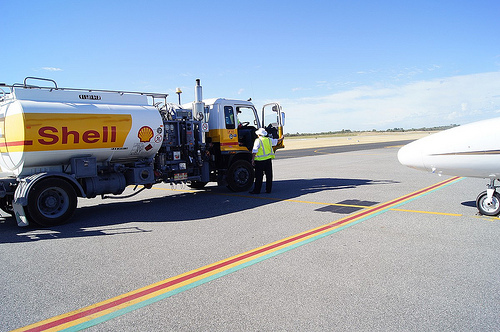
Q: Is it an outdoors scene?
A: Yes, it is outdoors.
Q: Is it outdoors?
A: Yes, it is outdoors.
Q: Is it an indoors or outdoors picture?
A: It is outdoors.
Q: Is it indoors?
A: No, it is outdoors.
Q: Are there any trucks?
A: Yes, there is a truck.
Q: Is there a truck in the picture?
A: Yes, there is a truck.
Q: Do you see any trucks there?
A: Yes, there is a truck.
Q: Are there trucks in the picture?
A: Yes, there is a truck.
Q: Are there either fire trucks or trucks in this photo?
A: Yes, there is a truck.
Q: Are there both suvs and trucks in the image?
A: No, there is a truck but no suvs.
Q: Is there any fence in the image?
A: No, there are no fences.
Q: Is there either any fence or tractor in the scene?
A: No, there are no fences or tractors.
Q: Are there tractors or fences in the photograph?
A: No, there are no fences or tractors.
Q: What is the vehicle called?
A: The vehicle is a truck.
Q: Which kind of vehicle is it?
A: The vehicle is a truck.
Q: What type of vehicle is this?
A: This is a truck.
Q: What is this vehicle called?
A: This is a truck.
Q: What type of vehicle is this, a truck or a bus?
A: This is a truck.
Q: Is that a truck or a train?
A: That is a truck.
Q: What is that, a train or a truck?
A: That is a truck.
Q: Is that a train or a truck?
A: That is a truck.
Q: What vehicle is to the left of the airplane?
A: The vehicle is a truck.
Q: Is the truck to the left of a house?
A: No, the truck is to the left of an airplane.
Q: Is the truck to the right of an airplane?
A: No, the truck is to the left of an airplane.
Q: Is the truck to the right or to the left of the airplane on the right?
A: The truck is to the left of the plane.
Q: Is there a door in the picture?
A: Yes, there is a door.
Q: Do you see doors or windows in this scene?
A: Yes, there is a door.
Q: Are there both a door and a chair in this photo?
A: No, there is a door but no chairs.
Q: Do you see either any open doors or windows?
A: Yes, there is an open door.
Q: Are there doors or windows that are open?
A: Yes, the door is open.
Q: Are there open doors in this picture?
A: Yes, there is an open door.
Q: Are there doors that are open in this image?
A: Yes, there is an open door.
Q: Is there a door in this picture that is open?
A: Yes, there is an open door.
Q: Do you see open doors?
A: Yes, there is an open door.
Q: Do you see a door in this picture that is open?
A: Yes, there is a door that is open.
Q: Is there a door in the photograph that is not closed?
A: Yes, there is a open door.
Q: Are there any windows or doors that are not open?
A: No, there is a door but it is open.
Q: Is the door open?
A: Yes, the door is open.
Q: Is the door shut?
A: No, the door is open.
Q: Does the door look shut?
A: No, the door is open.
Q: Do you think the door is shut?
A: No, the door is open.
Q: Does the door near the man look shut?
A: No, the door is open.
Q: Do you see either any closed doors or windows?
A: No, there is a door but it is open.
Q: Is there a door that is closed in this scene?
A: No, there is a door but it is open.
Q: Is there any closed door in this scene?
A: No, there is a door but it is open.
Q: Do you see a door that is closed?
A: No, there is a door but it is open.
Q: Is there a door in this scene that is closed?
A: No, there is a door but it is open.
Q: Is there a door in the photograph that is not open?
A: No, there is a door but it is open.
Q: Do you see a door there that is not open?
A: No, there is a door but it is open.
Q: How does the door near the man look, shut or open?
A: The door is open.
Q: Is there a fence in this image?
A: No, there are no fences.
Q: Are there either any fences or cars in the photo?
A: No, there are no fences or cars.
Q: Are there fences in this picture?
A: No, there are no fences.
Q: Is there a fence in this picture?
A: No, there are no fences.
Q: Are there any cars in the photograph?
A: No, there are no cars.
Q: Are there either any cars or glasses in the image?
A: No, there are no cars or glasses.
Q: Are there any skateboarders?
A: No, there are no skateboarders.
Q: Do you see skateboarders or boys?
A: No, there are no skateboarders or boys.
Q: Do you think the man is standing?
A: Yes, the man is standing.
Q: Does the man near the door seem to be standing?
A: Yes, the man is standing.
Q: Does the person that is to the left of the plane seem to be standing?
A: Yes, the man is standing.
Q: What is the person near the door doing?
A: The man is standing.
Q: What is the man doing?
A: The man is standing.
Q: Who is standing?
A: The man is standing.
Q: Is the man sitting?
A: No, the man is standing.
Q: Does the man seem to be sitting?
A: No, the man is standing.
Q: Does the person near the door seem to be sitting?
A: No, the man is standing.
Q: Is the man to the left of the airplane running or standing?
A: The man is standing.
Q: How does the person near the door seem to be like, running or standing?
A: The man is standing.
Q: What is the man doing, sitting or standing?
A: The man is standing.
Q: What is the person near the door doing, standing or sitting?
A: The man is standing.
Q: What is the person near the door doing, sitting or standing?
A: The man is standing.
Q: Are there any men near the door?
A: Yes, there is a man near the door.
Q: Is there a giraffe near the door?
A: No, there is a man near the door.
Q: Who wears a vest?
A: The man wears a vest.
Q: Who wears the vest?
A: The man wears a vest.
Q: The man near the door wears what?
A: The man wears a vest.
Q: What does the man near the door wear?
A: The man wears a vest.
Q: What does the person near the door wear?
A: The man wears a vest.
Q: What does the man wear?
A: The man wears a vest.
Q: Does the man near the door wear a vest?
A: Yes, the man wears a vest.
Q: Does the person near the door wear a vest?
A: Yes, the man wears a vest.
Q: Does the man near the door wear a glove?
A: No, the man wears a vest.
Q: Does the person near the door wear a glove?
A: No, the man wears a vest.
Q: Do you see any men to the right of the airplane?
A: No, the man is to the left of the airplane.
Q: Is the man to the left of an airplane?
A: Yes, the man is to the left of an airplane.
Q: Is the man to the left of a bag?
A: No, the man is to the left of an airplane.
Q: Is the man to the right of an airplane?
A: No, the man is to the left of an airplane.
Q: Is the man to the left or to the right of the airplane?
A: The man is to the left of the airplane.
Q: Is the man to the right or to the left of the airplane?
A: The man is to the left of the airplane.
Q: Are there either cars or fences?
A: No, there are no cars or fences.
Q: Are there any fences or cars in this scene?
A: No, there are no cars or fences.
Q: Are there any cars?
A: No, there are no cars.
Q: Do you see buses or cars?
A: No, there are no cars or buses.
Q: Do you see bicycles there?
A: No, there are no bicycles.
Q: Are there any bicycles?
A: No, there are no bicycles.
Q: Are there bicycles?
A: No, there are no bicycles.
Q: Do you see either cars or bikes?
A: No, there are no bikes or cars.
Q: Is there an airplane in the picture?
A: Yes, there is an airplane.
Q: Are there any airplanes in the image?
A: Yes, there is an airplane.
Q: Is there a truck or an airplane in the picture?
A: Yes, there is an airplane.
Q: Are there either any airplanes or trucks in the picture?
A: Yes, there is an airplane.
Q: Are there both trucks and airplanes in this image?
A: Yes, there are both an airplane and a truck.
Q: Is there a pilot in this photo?
A: No, there are no pilots.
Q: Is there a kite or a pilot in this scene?
A: No, there are no pilots or kites.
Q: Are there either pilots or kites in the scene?
A: No, there are no pilots or kites.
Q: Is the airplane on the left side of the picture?
A: No, the airplane is on the right of the image.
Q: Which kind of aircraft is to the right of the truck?
A: The aircraft is an airplane.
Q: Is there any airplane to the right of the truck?
A: Yes, there is an airplane to the right of the truck.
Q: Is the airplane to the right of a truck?
A: Yes, the airplane is to the right of a truck.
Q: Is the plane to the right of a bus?
A: No, the plane is to the right of a truck.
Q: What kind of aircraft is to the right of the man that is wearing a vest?
A: The aircraft is an airplane.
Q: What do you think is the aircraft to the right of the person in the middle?
A: The aircraft is an airplane.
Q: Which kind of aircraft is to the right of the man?
A: The aircraft is an airplane.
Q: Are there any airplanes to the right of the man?
A: Yes, there is an airplane to the right of the man.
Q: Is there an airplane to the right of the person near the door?
A: Yes, there is an airplane to the right of the man.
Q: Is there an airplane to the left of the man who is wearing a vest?
A: No, the airplane is to the right of the man.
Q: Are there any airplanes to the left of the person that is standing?
A: No, the airplane is to the right of the man.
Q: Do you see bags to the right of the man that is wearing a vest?
A: No, there is an airplane to the right of the man.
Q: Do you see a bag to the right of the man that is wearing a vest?
A: No, there is an airplane to the right of the man.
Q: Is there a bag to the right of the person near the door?
A: No, there is an airplane to the right of the man.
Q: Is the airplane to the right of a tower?
A: No, the airplane is to the right of the man.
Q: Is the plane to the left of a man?
A: No, the plane is to the right of a man.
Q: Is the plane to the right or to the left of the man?
A: The plane is to the right of the man.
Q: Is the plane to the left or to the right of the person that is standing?
A: The plane is to the right of the man.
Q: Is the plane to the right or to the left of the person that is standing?
A: The plane is to the right of the man.